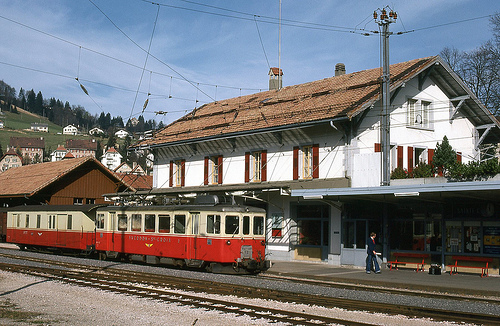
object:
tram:
[7, 205, 270, 274]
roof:
[128, 57, 438, 150]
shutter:
[313, 143, 318, 179]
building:
[129, 56, 499, 267]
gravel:
[407, 301, 411, 303]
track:
[0, 263, 381, 325]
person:
[364, 231, 383, 273]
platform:
[267, 258, 499, 298]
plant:
[429, 134, 459, 177]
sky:
[0, 0, 499, 124]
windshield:
[225, 214, 238, 233]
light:
[226, 241, 231, 246]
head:
[368, 231, 378, 238]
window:
[303, 147, 312, 157]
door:
[190, 211, 199, 259]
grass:
[0, 106, 141, 157]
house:
[63, 123, 83, 136]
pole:
[382, 26, 389, 184]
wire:
[144, 0, 372, 37]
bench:
[384, 251, 430, 273]